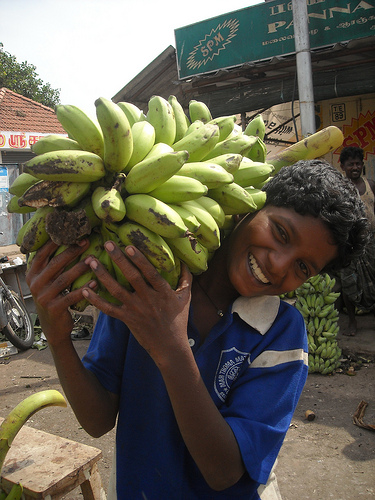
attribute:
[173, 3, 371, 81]
sign — green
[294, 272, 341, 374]
bananas — green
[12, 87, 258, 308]
bananas — large, green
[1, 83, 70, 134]
roof — red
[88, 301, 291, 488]
shirt — blue and white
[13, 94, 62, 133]
roof — red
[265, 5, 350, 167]
pole —   metal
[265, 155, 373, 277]
hair —  curly,  dark,  boy's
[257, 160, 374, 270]
curly hair —  black ,   curly,  boy's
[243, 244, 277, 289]
smile —  face's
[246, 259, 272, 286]
teeth — white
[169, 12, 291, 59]
sign — green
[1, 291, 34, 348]
wheel —  motorbike's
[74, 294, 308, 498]
shirt — white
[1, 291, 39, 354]
motorcycle tire —  motorcycle's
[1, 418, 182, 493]
stool — wooden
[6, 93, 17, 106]
tile — red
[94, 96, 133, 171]
banana — green